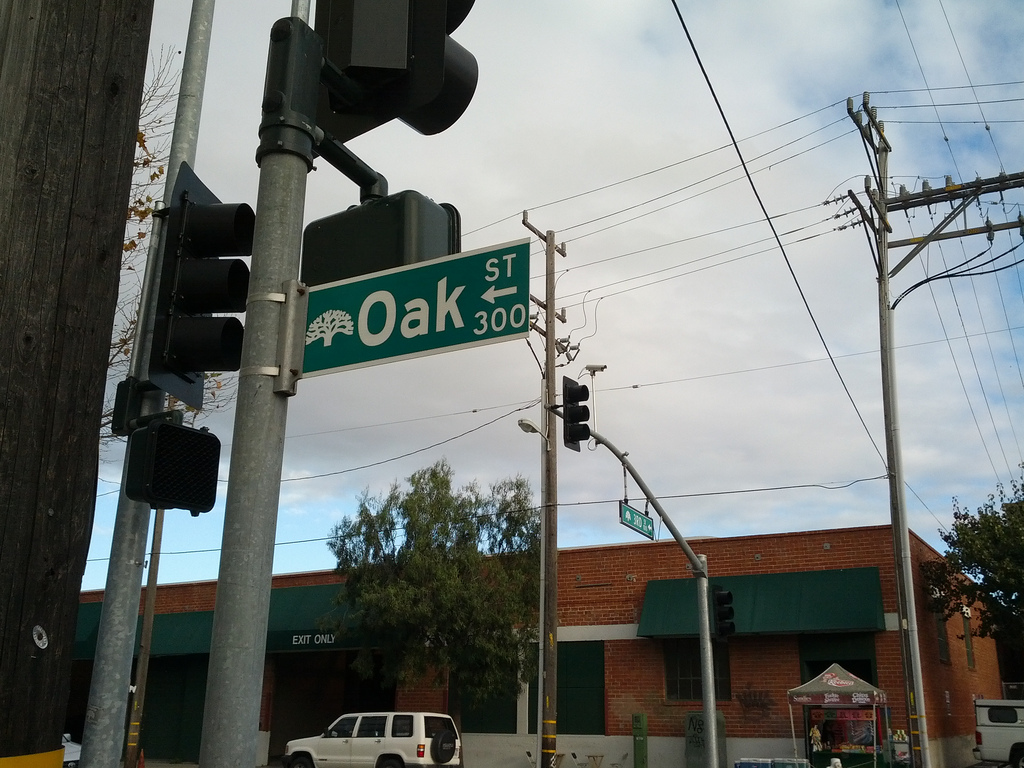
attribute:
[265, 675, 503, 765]
suv — white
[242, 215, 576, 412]
sign — green and white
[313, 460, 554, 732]
tree — green 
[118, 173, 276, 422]
signal — traffic